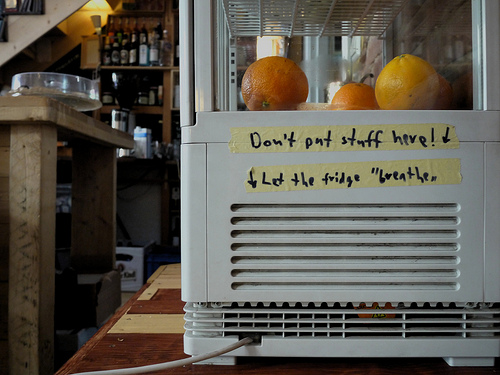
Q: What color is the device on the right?
A: White.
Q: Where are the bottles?
A: Back of the photo.